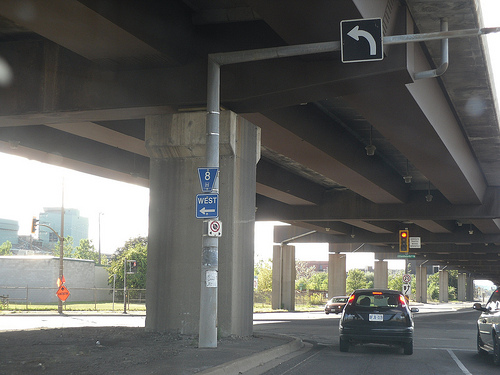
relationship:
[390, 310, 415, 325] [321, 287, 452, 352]
brake light on car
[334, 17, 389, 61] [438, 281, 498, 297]
sign signifying turn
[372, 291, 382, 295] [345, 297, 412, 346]
brake light on car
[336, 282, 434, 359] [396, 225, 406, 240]
car stopped at red light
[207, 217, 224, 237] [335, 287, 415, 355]
sign in front of car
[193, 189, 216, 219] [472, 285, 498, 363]
sign in front of car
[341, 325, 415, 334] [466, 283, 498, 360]
bumper of moving car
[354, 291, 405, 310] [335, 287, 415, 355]
back window of car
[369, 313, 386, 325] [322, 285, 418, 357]
license tag of car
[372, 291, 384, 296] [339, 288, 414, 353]
brake light of car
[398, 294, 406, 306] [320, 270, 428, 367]
brake light on car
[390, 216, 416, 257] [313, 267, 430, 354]
signal for car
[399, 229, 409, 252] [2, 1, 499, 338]
signal under bridge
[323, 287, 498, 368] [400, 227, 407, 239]
cars stopped at street light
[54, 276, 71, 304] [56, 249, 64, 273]
sign on pole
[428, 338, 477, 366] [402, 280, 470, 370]
marker painted on street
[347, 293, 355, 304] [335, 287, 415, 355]
brake light on car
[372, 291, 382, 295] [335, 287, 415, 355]
brake light on car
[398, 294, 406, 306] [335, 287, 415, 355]
brake light on car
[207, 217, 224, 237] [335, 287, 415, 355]
sign for car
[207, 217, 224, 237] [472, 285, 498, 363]
sign for car